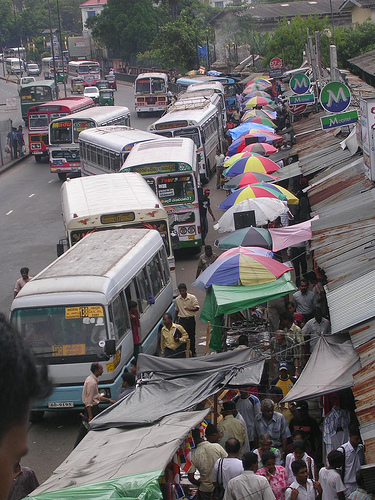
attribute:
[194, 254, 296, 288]
umbrella — green, black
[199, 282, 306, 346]
tarp — green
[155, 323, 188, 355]
shirt — yellow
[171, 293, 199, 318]
shirt — yellow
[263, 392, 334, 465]
shirt — blue , navy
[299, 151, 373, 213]
roof — rusty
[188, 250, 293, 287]
umbrella — multicolor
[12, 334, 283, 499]
tarp — grey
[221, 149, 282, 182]
umbrella — black, red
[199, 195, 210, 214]
shirt — black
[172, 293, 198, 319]
shirt — black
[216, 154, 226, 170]
shirt — black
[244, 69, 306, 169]
umbrella — white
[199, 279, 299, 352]
tarp — green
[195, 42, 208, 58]
banner — blue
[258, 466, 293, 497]
shirt — pink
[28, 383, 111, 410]
bumper — blue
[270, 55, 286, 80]
sign — blue, green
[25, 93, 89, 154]
bus — red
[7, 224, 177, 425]
bus — white, blue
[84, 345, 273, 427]
tarp — gray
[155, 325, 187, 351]
shirt — yellow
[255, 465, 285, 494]
shirt — pink